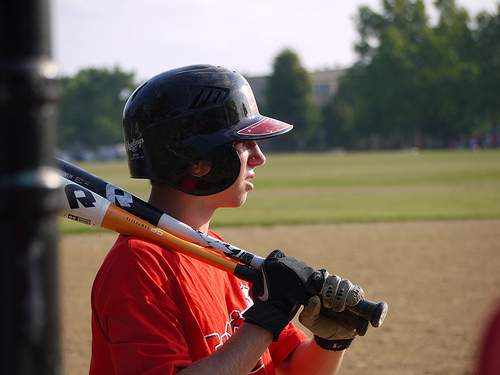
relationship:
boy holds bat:
[67, 55, 354, 365] [57, 174, 369, 336]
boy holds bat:
[67, 55, 354, 365] [52, 152, 389, 327]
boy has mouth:
[67, 55, 354, 365] [242, 175, 260, 189]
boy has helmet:
[67, 55, 354, 365] [112, 62, 296, 196]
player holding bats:
[82, 62, 366, 373] [37, 160, 417, 337]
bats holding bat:
[37, 160, 417, 337] [72, 182, 306, 294]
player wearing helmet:
[82, 62, 366, 373] [109, 53, 301, 193]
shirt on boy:
[78, 225, 314, 374] [67, 55, 354, 365]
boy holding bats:
[67, 55, 354, 365] [39, 130, 379, 357]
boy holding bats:
[67, 55, 354, 365] [47, 169, 235, 259]